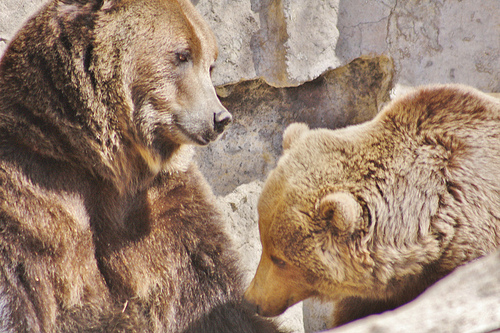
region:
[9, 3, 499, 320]
a couple of bears at the zoo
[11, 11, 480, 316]
two bears at a zoo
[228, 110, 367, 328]
the head of a bear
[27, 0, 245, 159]
the head of a bear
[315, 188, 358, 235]
the ear of a bear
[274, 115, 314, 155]
the ear of a bear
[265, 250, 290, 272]
the eye of a bear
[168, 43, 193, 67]
the eye of a bear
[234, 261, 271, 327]
the nose of a bear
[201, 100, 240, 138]
the nose of a bear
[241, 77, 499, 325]
Young bear looking down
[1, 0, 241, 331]
Mature bear with head lifted up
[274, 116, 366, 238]
Pair of short bear ears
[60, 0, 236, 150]
Head of a bear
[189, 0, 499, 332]
Rock face in the background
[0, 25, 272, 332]
Thick fur on a bear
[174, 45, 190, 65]
Brown eye of a bear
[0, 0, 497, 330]
Two bears in proximity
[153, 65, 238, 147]
Snout of a bear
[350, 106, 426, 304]
Short neck of a bear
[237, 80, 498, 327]
brown baby bear with mother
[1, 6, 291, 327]
brown mother bear with baby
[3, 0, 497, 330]
two bears facing each other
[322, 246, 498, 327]
large grey rock beside baby bear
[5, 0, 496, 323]
outdoor sunny zoo scene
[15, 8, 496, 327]
grey rocky exterior scene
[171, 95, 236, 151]
black nose of mother bear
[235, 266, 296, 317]
light brown nose of baby bear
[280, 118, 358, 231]
light brown ears of baby bear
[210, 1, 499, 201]
sunlight reflecting on rocks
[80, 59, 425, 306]
the bears are looking at each other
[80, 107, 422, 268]
the bears are brown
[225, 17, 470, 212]
the rock is behind the bears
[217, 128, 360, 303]
the bear is looking down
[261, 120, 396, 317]
the bear has two ears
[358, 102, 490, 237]
the bear has soft fur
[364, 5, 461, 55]
the wall has cracks in it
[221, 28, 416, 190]
the wall is made of stone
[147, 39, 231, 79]
the bear has brown eyes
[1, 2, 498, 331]
two large bears in the shot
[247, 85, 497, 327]
the bear on right is light brown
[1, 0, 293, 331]
bear on left is dark brown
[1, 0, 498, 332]
rock wall behind bears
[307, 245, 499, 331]
rock in front of bear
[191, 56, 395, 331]
curved in section of rock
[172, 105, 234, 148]
black nose and mouth on bear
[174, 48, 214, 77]
bear has eyes open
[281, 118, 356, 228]
fuzzy small ears on bear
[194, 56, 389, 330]
shadow section of rock wall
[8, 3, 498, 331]
Two big brown bears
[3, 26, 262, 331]
Large brown bear has a thick coat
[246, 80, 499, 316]
Light brown bear in the sunlight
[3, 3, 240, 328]
A large brown bear with a thick coat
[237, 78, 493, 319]
A light brown bear with a thick coat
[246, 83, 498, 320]
A light brown bear with fuzzy ears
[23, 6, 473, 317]
The two brown bears and their fuzzy coats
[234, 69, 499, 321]
small bear looking at fur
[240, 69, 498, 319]
bear on right is small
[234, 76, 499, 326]
bear on right is small brown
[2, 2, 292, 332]
bear looking at small bear